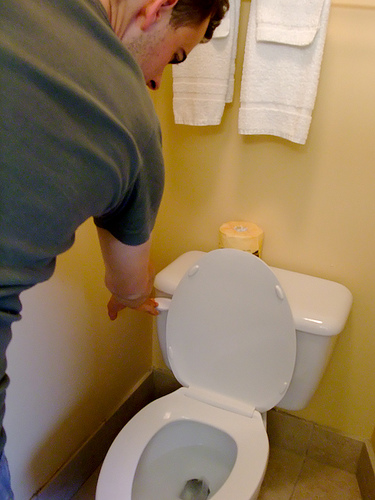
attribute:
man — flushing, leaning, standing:
[8, 9, 194, 326]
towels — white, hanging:
[220, 2, 328, 144]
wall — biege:
[277, 163, 358, 257]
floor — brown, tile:
[292, 436, 356, 491]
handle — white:
[142, 295, 172, 324]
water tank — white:
[279, 279, 349, 414]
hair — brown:
[172, 5, 218, 25]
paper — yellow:
[207, 216, 295, 251]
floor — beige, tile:
[69, 391, 373, 499]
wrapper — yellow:
[217, 220, 263, 259]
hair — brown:
[172, 0, 231, 40]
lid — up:
[164, 249, 296, 417]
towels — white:
[180, 77, 318, 133]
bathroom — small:
[7, 2, 373, 498]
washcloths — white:
[213, 22, 321, 44]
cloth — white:
[252, 0, 325, 48]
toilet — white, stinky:
[89, 245, 357, 498]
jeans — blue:
[1, 440, 15, 499]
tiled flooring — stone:
[80, 443, 360, 497]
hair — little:
[180, 0, 233, 30]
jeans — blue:
[3, 371, 22, 498]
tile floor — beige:
[283, 447, 341, 488]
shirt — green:
[6, 6, 162, 317]